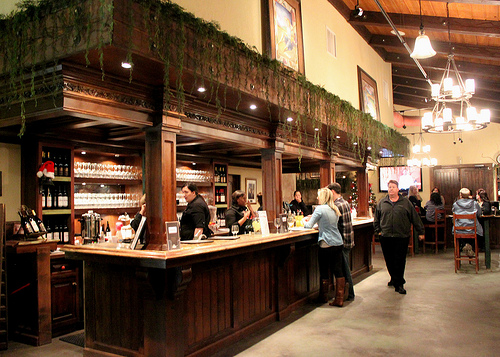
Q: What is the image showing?
A: It is showing a restaurant.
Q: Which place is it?
A: It is a restaurant.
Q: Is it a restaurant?
A: Yes, it is a restaurant.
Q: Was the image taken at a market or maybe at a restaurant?
A: It was taken at a restaurant.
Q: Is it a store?
A: No, it is a restaurant.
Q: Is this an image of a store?
A: No, the picture is showing a restaurant.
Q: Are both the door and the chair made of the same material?
A: Yes, both the door and the chair are made of wood.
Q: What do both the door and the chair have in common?
A: The material, both the door and the chair are wooden.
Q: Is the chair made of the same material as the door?
A: Yes, both the chair and the door are made of wood.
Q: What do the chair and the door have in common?
A: The material, both the chair and the door are wooden.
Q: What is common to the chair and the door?
A: The material, both the chair and the door are wooden.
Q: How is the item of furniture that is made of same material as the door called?
A: The piece of furniture is a chair.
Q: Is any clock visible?
A: No, there are no clocks.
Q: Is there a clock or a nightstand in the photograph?
A: No, there are no clocks or nightstands.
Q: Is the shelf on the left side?
A: Yes, the shelf is on the left of the image.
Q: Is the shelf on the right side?
A: No, the shelf is on the left of the image.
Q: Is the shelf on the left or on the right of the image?
A: The shelf is on the left of the image.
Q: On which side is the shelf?
A: The shelf is on the left of the image.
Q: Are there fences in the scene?
A: No, there are no fences.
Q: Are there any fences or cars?
A: No, there are no fences or cars.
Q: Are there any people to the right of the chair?
A: No, the person is to the left of the chair.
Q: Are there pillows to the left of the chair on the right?
A: No, there is a person to the left of the chair.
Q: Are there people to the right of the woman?
A: Yes, there is a person to the right of the woman.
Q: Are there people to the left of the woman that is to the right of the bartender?
A: No, the person is to the right of the woman.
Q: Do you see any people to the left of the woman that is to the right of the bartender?
A: No, the person is to the right of the woman.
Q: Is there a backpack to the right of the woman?
A: No, there is a person to the right of the woman.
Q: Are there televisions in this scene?
A: Yes, there is a television.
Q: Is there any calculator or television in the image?
A: Yes, there is a television.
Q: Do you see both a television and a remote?
A: No, there is a television but no remote controls.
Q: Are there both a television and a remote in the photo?
A: No, there is a television but no remote controls.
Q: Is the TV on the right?
A: Yes, the TV is on the right of the image.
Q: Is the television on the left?
A: No, the television is on the right of the image.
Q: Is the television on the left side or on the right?
A: The television is on the right of the image.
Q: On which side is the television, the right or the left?
A: The television is on the right of the image.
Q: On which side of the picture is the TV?
A: The TV is on the right of the image.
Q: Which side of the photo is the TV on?
A: The TV is on the right of the image.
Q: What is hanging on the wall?
A: The television is hanging on the wall.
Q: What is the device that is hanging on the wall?
A: The device is a television.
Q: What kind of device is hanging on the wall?
A: The device is a television.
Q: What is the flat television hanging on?
A: The television is hanging on the wall.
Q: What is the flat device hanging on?
A: The television is hanging on the wall.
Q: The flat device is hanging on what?
A: The television is hanging on the wall.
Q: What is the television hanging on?
A: The television is hanging on the wall.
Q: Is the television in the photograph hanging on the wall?
A: Yes, the television is hanging on the wall.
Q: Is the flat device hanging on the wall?
A: Yes, the television is hanging on the wall.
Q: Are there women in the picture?
A: Yes, there is a woman.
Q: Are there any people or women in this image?
A: Yes, there is a woman.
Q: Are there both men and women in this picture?
A: Yes, there are both a woman and a man.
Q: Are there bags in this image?
A: No, there are no bags.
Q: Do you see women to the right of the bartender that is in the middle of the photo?
A: Yes, there is a woman to the right of the bartender.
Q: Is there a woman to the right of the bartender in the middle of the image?
A: Yes, there is a woman to the right of the bartender.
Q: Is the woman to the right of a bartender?
A: Yes, the woman is to the right of a bartender.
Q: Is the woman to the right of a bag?
A: No, the woman is to the right of a bartender.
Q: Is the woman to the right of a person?
A: No, the woman is to the left of a person.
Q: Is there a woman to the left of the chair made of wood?
A: Yes, there is a woman to the left of the chair.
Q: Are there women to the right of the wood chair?
A: No, the woman is to the left of the chair.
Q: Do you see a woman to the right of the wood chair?
A: No, the woman is to the left of the chair.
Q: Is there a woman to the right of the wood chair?
A: No, the woman is to the left of the chair.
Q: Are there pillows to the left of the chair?
A: No, there is a woman to the left of the chair.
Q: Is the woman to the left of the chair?
A: Yes, the woman is to the left of the chair.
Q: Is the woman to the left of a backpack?
A: No, the woman is to the left of the chair.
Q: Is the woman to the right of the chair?
A: No, the woman is to the left of the chair.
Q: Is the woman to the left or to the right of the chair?
A: The woman is to the left of the chair.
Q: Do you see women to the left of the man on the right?
A: Yes, there is a woman to the left of the man.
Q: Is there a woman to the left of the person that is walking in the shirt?
A: Yes, there is a woman to the left of the man.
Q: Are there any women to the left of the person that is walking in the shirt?
A: Yes, there is a woman to the left of the man.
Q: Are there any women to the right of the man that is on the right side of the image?
A: No, the woman is to the left of the man.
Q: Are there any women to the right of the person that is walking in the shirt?
A: No, the woman is to the left of the man.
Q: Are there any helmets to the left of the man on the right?
A: No, there is a woman to the left of the man.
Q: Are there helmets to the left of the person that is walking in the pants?
A: No, there is a woman to the left of the man.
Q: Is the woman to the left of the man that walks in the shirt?
A: Yes, the woman is to the left of the man.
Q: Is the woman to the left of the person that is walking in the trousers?
A: Yes, the woman is to the left of the man.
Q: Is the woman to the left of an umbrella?
A: No, the woman is to the left of the man.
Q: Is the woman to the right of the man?
A: No, the woman is to the left of the man.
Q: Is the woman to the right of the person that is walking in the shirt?
A: No, the woman is to the left of the man.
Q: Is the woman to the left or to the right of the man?
A: The woman is to the left of the man.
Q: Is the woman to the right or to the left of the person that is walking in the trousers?
A: The woman is to the left of the man.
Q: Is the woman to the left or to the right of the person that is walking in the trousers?
A: The woman is to the left of the man.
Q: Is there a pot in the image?
A: No, there are no pots.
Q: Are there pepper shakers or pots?
A: No, there are no pots or pepper shakers.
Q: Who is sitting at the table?
A: The couple is sitting at the table.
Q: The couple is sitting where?
A: The couple is sitting at the table.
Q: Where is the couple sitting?
A: The couple is sitting at the table.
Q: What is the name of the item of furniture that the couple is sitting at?
A: The piece of furniture is a table.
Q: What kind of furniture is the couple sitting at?
A: The couple is sitting at the table.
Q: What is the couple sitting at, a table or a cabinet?
A: The couple is sitting at a table.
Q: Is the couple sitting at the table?
A: Yes, the couple is sitting at the table.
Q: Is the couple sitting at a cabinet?
A: No, the couple is sitting at the table.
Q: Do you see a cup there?
A: No, there are no cups.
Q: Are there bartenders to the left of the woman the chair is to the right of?
A: Yes, there is a bartender to the left of the woman.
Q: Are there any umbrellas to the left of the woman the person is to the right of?
A: No, there is a bartender to the left of the woman.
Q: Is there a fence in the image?
A: No, there are no fences.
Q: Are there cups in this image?
A: No, there are no cups.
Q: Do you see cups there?
A: No, there are no cups.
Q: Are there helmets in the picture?
A: No, there are no helmets.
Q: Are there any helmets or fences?
A: No, there are no helmets or fences.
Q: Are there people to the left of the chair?
A: Yes, there is a person to the left of the chair.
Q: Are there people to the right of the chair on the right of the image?
A: No, the person is to the left of the chair.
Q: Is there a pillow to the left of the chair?
A: No, there is a person to the left of the chair.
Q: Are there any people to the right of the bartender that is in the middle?
A: Yes, there is a person to the right of the bartender.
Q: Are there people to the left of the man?
A: Yes, there is a person to the left of the man.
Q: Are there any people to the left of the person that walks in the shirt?
A: Yes, there is a person to the left of the man.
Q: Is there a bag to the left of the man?
A: No, there is a person to the left of the man.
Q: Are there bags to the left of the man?
A: No, there is a person to the left of the man.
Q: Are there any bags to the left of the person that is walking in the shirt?
A: No, there is a person to the left of the man.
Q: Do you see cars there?
A: No, there are no cars.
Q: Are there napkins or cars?
A: No, there are no cars or napkins.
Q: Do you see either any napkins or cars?
A: No, there are no cars or napkins.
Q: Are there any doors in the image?
A: Yes, there is a door.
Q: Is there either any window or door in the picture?
A: Yes, there is a door.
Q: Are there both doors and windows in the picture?
A: No, there is a door but no windows.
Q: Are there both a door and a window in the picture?
A: No, there is a door but no windows.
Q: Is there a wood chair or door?
A: Yes, there is a wood door.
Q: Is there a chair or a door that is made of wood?
A: Yes, the door is made of wood.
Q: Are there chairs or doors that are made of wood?
A: Yes, the door is made of wood.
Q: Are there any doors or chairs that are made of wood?
A: Yes, the door is made of wood.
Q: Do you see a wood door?
A: Yes, there is a wood door.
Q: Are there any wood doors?
A: Yes, there is a wood door.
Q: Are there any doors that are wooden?
A: Yes, there is a door that is wooden.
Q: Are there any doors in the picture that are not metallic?
A: Yes, there is a wooden door.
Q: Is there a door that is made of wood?
A: Yes, there is a door that is made of wood.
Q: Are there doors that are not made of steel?
A: Yes, there is a door that is made of wood.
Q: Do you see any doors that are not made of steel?
A: Yes, there is a door that is made of wood.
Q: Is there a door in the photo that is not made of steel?
A: Yes, there is a door that is made of wood.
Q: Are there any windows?
A: No, there are no windows.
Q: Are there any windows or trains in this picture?
A: No, there are no windows or trains.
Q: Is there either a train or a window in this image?
A: No, there are no windows or trains.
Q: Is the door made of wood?
A: Yes, the door is made of wood.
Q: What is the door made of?
A: The door is made of wood.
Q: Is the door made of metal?
A: No, the door is made of wood.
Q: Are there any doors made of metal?
A: No, there is a door but it is made of wood.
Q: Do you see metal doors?
A: No, there is a door but it is made of wood.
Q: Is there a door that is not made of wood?
A: No, there is a door but it is made of wood.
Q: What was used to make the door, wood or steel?
A: The door is made of wood.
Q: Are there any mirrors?
A: No, there are no mirrors.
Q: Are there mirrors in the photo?
A: No, there are no mirrors.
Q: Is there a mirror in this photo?
A: No, there are no mirrors.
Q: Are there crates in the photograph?
A: No, there are no crates.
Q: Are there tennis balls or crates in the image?
A: No, there are no crates or tennis balls.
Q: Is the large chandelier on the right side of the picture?
A: Yes, the chandelier is on the right of the image.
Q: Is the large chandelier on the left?
A: No, the chandelier is on the right of the image.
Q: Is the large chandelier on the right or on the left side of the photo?
A: The chandelier is on the right of the image.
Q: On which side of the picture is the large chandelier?
A: The chandelier is on the right of the image.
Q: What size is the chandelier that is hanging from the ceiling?
A: The chandelier is large.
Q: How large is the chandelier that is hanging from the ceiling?
A: The chandelier is large.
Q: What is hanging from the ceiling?
A: The chandelier is hanging from the ceiling.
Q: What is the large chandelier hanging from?
A: The chandelier is hanging from the ceiling.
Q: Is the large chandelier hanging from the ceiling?
A: Yes, the chandelier is hanging from the ceiling.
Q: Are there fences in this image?
A: No, there are no fences.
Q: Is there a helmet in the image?
A: No, there are no helmets.